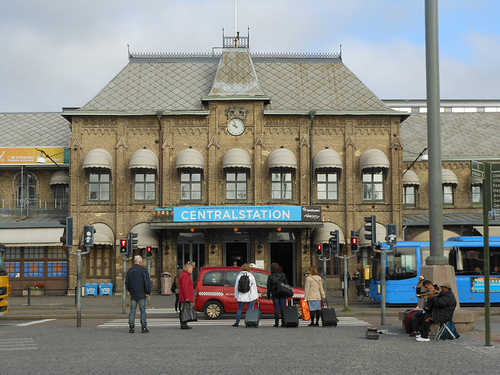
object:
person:
[304, 266, 327, 328]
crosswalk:
[99, 313, 371, 327]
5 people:
[124, 254, 327, 334]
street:
[4, 270, 465, 317]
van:
[192, 266, 323, 319]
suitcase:
[244, 301, 262, 328]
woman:
[266, 262, 293, 327]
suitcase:
[320, 298, 339, 328]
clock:
[226, 117, 246, 137]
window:
[125, 147, 164, 204]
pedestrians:
[178, 263, 195, 330]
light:
[120, 240, 127, 247]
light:
[363, 215, 372, 223]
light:
[364, 233, 372, 240]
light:
[351, 236, 359, 245]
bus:
[368, 236, 500, 307]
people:
[404, 276, 441, 332]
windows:
[82, 148, 113, 204]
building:
[0, 0, 500, 298]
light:
[364, 225, 372, 231]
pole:
[381, 247, 387, 324]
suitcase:
[280, 298, 300, 328]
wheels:
[283, 324, 287, 327]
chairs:
[433, 320, 458, 342]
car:
[192, 265, 312, 320]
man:
[124, 255, 153, 333]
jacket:
[124, 263, 151, 300]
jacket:
[178, 270, 196, 303]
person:
[232, 263, 261, 327]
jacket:
[234, 270, 259, 303]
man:
[416, 283, 458, 343]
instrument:
[417, 292, 437, 300]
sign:
[173, 204, 302, 221]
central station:
[181, 209, 292, 219]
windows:
[44, 245, 68, 279]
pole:
[425, 0, 445, 255]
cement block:
[417, 263, 461, 312]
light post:
[74, 248, 82, 327]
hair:
[134, 255, 142, 265]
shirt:
[125, 263, 151, 300]